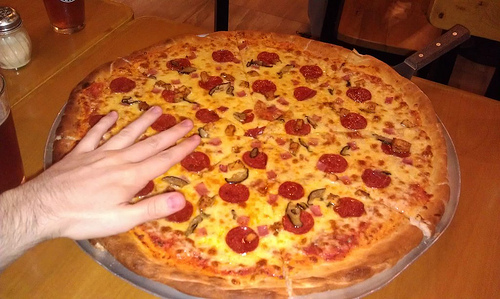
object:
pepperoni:
[340, 112, 368, 129]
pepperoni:
[195, 108, 221, 123]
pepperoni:
[198, 71, 224, 90]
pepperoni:
[224, 225, 261, 254]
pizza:
[52, 29, 450, 297]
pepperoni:
[277, 181, 306, 199]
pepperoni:
[284, 117, 311, 136]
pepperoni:
[109, 77, 136, 93]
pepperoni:
[361, 168, 392, 189]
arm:
[0, 104, 204, 265]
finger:
[133, 191, 186, 222]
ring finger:
[101, 105, 164, 150]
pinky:
[73, 110, 119, 150]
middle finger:
[120, 117, 194, 162]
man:
[0, 102, 202, 279]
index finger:
[136, 134, 201, 181]